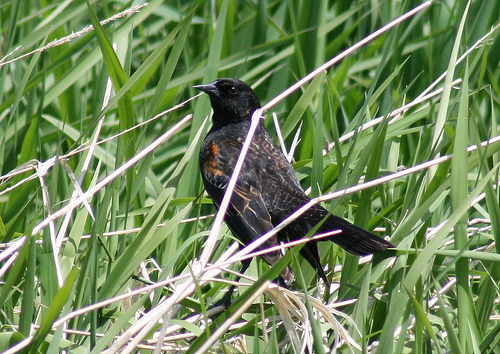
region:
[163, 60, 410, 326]
A black bird in grass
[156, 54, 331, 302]
a bird is i the middle of trees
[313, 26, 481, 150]
tree branches are green in color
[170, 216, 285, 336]
some branches are dried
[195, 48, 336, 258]
the bird is looking in the air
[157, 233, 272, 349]
the branches are gray in colo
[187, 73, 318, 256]
the bird is black in color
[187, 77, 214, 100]
the beak is black incolor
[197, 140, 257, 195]
feathers have some orange parts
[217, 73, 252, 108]
the eyes ar open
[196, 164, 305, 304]
bird is standing on a branch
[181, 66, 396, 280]
black bird in the grass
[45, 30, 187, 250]
lots of tall green grass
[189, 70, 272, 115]
head of a black bird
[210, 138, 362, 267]
feathers on a small bird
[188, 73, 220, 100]
beak of a bird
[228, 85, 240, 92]
little black eye on a bird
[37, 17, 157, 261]
pieces of tall green grass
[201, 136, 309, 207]
orange spots on a feather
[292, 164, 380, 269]
tail feathers on a bird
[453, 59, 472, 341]
tall blade of green grass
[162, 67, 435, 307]
bird in the grass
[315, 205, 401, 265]
black feathers on the tail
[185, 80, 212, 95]
pointy black beak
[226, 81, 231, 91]
black eye on the side of the face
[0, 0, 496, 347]
grass on the ground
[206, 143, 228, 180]
traces of orange on the bird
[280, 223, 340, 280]
black feather hanging down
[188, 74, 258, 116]
the bird's head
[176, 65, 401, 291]
black and orange bird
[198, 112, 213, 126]
tip of the blade of glass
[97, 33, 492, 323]
a bird in the grass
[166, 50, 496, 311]
a small bird in the grass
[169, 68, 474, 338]
a black bird in the grass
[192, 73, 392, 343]
a bird in the green grass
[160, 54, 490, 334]
a small bird in the green grass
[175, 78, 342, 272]
a black bird in the green grass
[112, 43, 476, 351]
grass with a bird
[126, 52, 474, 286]
grass with a small bird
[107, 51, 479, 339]
a bird standin goutside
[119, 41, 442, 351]
a small bird standing outside